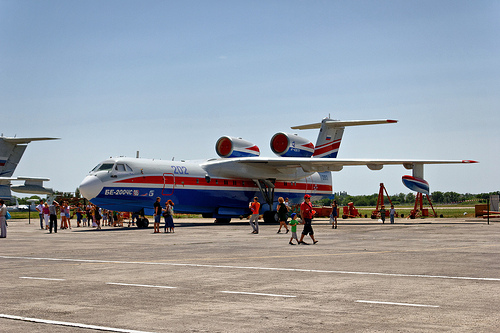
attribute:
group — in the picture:
[152, 197, 174, 232]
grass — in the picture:
[0, 200, 499, 223]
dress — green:
[276, 209, 307, 260]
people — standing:
[65, 189, 486, 237]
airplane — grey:
[1, 110, 63, 237]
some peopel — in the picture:
[34, 188, 351, 253]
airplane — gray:
[71, 110, 482, 225]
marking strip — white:
[19, 276, 66, 281]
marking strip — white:
[104, 280, 177, 290]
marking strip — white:
[221, 287, 298, 297]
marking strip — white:
[356, 294, 438, 308]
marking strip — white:
[0, 250, 499, 285]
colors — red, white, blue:
[143, 136, 350, 211]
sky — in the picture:
[0, 0, 499, 190]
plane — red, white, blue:
[69, 108, 488, 233]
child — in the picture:
[281, 212, 302, 246]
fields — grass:
[3, 204, 498, 224]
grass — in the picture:
[441, 207, 459, 215]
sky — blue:
[248, 23, 397, 98]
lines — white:
[166, 233, 406, 293]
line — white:
[4, 249, 497, 330]